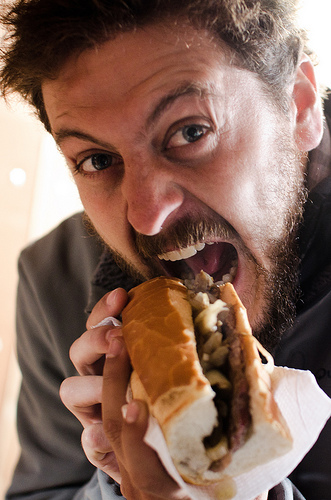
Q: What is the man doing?
A: Eating.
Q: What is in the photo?
A: The man's eyes.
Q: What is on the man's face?
A: A beard and mustache.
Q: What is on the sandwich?
A: Cheese and meat.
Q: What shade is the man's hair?
A: Dark.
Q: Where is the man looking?
A: Directly at camera.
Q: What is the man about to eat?
A: A sandwich.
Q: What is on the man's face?
A: A beard.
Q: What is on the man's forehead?
A: Wrinkles.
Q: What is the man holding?
A: A sandwich.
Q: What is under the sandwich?
A: White napkin.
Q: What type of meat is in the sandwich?
A: Brown meat.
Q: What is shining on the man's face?
A: Sun light.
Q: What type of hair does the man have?
A: Short brown.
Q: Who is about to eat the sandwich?
A: Man with grey coat.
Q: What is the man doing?
A: Eating a sandwich.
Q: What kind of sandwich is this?
A: Philly cheese steak.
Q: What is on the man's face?
A: Beard and mustache.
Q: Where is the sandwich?
A: In front of the man's mouth.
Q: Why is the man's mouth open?
A: Because he is about to take a bite.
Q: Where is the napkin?
A: Around the sandwich.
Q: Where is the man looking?
A: At the camera.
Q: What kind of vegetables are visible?
A: Onions and green peppers.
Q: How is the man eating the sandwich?
A: With his hands.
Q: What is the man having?
A: Face.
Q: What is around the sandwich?
A: Napkin.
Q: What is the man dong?
A: Eating.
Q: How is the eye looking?
A: Wrinkled.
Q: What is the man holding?
A: Cake.